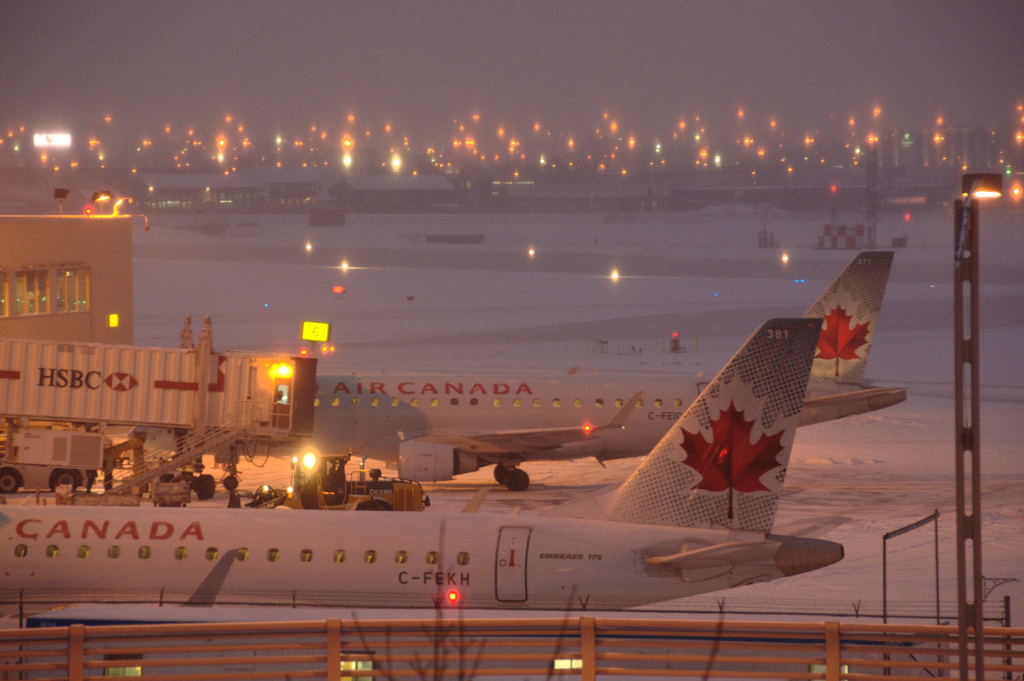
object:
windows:
[139, 546, 153, 559]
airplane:
[0, 317, 844, 611]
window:
[457, 552, 470, 566]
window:
[395, 550, 408, 564]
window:
[299, 549, 313, 562]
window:
[236, 547, 249, 561]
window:
[173, 546, 187, 560]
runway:
[0, 244, 1024, 681]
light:
[610, 267, 619, 283]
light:
[781, 252, 787, 262]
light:
[340, 260, 348, 273]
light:
[306, 240, 312, 252]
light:
[528, 246, 534, 256]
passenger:
[276, 390, 282, 400]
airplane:
[128, 250, 906, 491]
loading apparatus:
[0, 339, 318, 437]